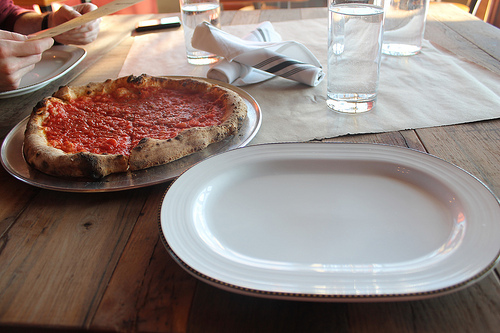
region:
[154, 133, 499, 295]
a white plate on a table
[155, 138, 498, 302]
a white plate on a wooden table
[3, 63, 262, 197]
a pizza on a plate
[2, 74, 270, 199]
a pizza on a metal plate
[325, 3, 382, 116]
a cup on a table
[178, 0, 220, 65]
a glass on a table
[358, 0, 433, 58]
a glass on a table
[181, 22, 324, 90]
a napkin on a table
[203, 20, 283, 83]
a napkin on a table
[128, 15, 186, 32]
a phone on a table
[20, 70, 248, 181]
Pizza on a tray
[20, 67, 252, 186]
Pizza is on a tray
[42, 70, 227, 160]
Sauce on a pizza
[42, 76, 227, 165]
Sauce is on a pizza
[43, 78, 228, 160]
Tomato sauce on a pizza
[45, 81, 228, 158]
Tomato sauce is on a pizza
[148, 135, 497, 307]
Plate is on a table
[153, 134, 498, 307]
White plate on a table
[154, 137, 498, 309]
White plate is on a table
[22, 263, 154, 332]
A raw wooden table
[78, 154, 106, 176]
Burnt crust of a pie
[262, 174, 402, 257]
Flats surface of a plate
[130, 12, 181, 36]
A cellphone in the background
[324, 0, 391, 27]
A glass full of water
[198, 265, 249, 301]
Edge of the white plated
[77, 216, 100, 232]
A hole on the table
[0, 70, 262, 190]
pizza on a silver pan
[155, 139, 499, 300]
the plate is shaped like an oval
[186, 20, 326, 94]
the napkins are rolled up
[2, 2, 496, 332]
the table is wooden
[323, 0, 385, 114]
a glass of water on the table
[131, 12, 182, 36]
a cell phone on the table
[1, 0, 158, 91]
hands holding a menu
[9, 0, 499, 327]
the table is brown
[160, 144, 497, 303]
the plate is white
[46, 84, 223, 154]
the sauce is red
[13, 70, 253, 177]
DELICIOUS BAKED PIZZA PIE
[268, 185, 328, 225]
PART OF WHITE SERVING PLATE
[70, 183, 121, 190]
PART OF METAL COOKING PLATE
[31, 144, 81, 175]
BART OF COOKED PIZZA CRUST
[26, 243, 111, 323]
PART OF WOODEN SERVING TABL;E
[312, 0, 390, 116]
CLEAR GLASS OF WATER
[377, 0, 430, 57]
WATER IN CLEAR GLASS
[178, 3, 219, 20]
PART OF WATER IN GLASS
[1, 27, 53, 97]
HAND OF EATING PERSON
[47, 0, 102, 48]
HAND OF EATING PERSON